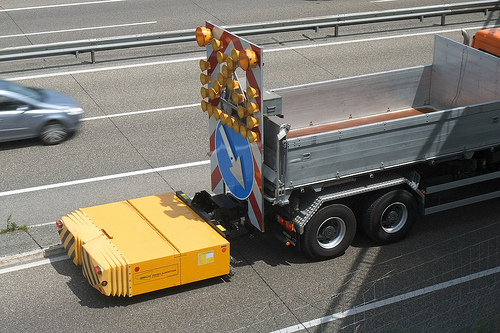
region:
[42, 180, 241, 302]
a large elecronic sign on the ground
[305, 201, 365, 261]
black truck tire and silver rim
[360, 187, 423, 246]
black truck tire and silver rim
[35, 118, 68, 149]
black car tire and silver rim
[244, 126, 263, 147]
yellow electronic light on a sign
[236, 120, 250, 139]
yellow electronic light on a sign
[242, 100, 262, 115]
yellow electronic light on a sign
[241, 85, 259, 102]
yellow electronic light on a sign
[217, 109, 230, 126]
yellow electronic light on a sign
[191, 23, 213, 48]
yellow electronic light on a sign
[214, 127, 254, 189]
white arrow on a sign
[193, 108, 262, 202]
blue circle sign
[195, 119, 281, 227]
sign is red and white stripes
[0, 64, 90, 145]
car driving by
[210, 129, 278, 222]
signs onthe back of a truck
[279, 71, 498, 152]
bed of truck is empty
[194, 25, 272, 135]
yellow lights on the truck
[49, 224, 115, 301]
black and yellow stripes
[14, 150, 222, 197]
solid white line on the road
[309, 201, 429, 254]
two wheels on the back of the truck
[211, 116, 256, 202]
the arrow pointing to the ground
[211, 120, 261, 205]
the blue circle with the arrow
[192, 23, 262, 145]
the yellow signals on the truck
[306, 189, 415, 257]
the tires on the back of the truck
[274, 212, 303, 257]
the red lights on the tail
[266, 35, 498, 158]
the bed of the truck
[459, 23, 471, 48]
the exhaust on the truck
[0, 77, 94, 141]
the car on the road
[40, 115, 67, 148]
the rim of the tire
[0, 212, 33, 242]
the grass growing on the line on the road